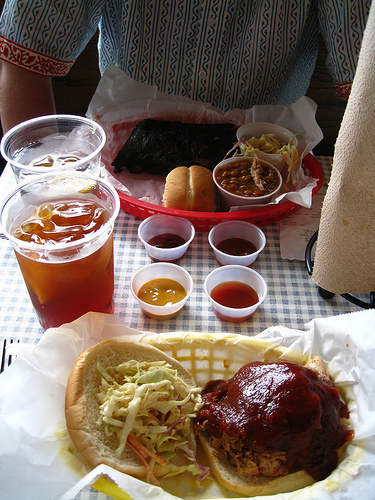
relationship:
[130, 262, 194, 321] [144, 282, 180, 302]
containers of mustard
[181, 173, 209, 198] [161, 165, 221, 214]
top of bun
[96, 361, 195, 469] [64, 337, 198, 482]
coleslaw on bun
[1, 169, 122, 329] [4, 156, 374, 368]
cup on table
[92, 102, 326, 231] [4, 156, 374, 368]
basket on table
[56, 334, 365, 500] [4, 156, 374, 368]
basket on table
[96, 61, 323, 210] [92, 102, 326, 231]
paper in basket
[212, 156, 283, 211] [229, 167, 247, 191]
dish of beans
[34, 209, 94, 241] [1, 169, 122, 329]
ice in cup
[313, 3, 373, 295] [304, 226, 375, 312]
paper towel on rack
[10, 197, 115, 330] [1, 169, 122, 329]
drink in cup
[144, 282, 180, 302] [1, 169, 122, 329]
mustard in cup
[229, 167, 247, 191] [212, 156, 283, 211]
beans in dish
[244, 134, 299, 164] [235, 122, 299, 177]
coleslaw in dish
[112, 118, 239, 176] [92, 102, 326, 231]
meat in basket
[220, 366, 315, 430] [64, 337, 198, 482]
sauce on bun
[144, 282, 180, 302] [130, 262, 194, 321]
mustard in containers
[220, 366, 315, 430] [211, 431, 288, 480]
sauce on meat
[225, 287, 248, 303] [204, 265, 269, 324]
sauce in container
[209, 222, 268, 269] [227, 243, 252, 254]
cup with sauce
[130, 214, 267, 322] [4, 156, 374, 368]
containers on table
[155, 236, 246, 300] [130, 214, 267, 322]
sauces in containers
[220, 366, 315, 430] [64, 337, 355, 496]
sauce on sandwich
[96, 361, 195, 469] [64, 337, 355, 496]
coleslaw on sandwich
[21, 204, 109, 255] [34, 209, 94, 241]
drink with ice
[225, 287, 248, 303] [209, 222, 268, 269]
sauce in cup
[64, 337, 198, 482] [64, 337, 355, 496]
bun of sandwich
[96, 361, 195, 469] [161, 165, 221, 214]
coleslaw on bun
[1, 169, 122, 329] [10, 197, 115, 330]
cup of drink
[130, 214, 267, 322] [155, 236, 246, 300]
containers of sauces